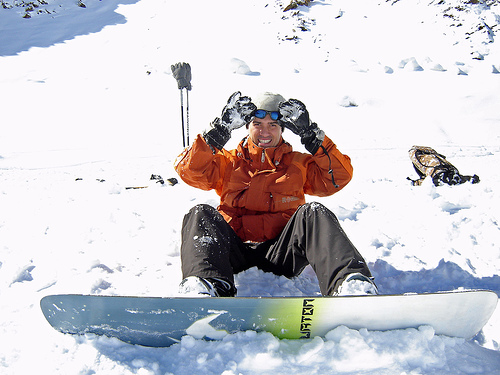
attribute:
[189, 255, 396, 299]
boot — snow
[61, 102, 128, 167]
snow — white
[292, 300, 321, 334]
writing — black